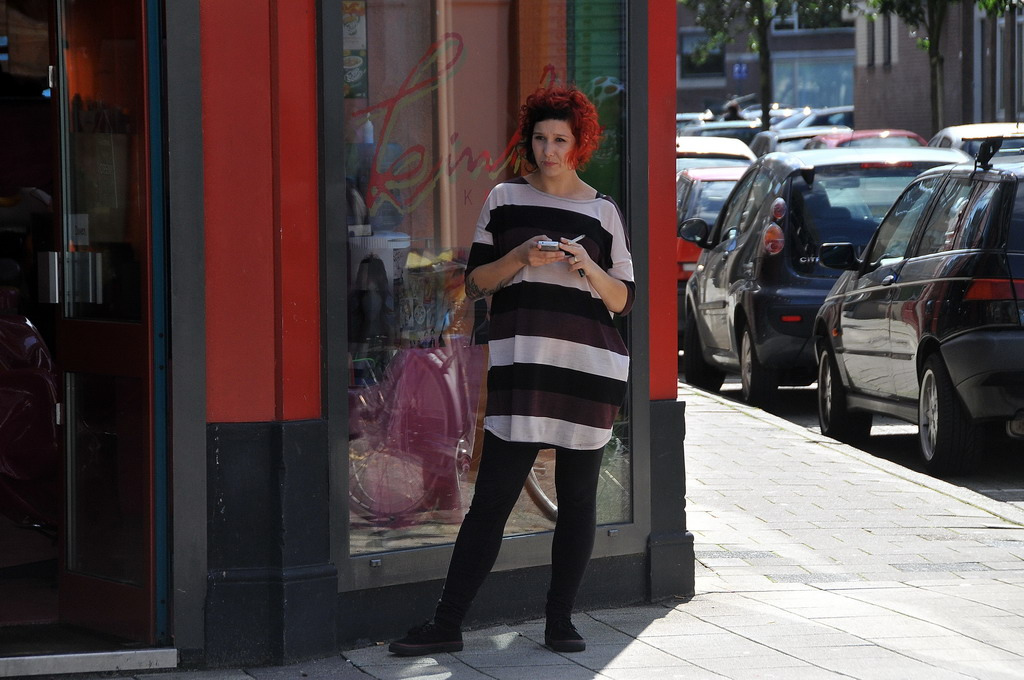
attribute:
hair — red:
[516, 87, 608, 176]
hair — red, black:
[513, 82, 600, 181]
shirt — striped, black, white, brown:
[463, 178, 637, 460]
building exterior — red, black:
[191, 4, 332, 673]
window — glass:
[317, 4, 641, 537]